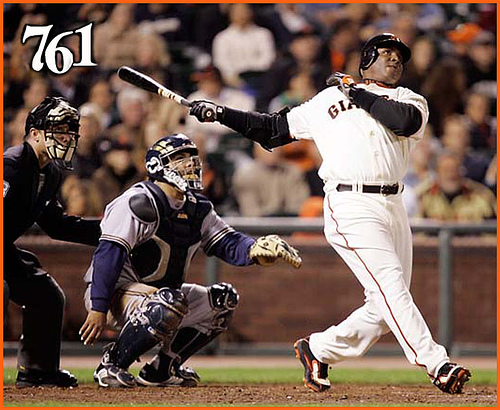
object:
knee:
[378, 259, 403, 284]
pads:
[206, 281, 240, 311]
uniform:
[0, 140, 102, 370]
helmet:
[358, 32, 412, 79]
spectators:
[3, 3, 496, 224]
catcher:
[78, 131, 305, 388]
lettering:
[326, 94, 390, 120]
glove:
[248, 234, 302, 270]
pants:
[308, 185, 451, 386]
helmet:
[22, 94, 81, 173]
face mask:
[43, 101, 81, 174]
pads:
[141, 287, 190, 335]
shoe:
[292, 336, 331, 392]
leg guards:
[98, 281, 239, 374]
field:
[0, 328, 496, 407]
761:
[21, 22, 99, 76]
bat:
[117, 66, 215, 119]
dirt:
[1, 382, 496, 405]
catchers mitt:
[246, 230, 305, 272]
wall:
[1, 217, 498, 357]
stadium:
[3, 2, 498, 410]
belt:
[337, 180, 406, 195]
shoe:
[430, 361, 472, 395]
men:
[1, 96, 106, 389]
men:
[188, 30, 473, 397]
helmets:
[144, 132, 205, 194]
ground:
[3, 354, 494, 407]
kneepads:
[141, 285, 189, 342]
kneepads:
[206, 281, 241, 337]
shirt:
[286, 77, 430, 184]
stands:
[3, 3, 498, 248]